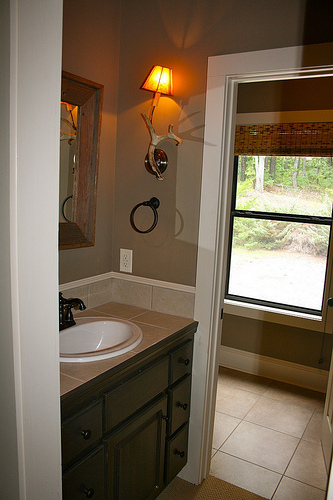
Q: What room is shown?
A: Bathroom.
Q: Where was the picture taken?
A: In a bathroom.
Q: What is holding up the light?
A: A antler.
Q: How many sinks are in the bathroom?
A: 1.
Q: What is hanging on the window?
A: Blinds.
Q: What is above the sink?
A: A mirror.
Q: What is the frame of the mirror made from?
A: Wood.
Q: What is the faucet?
A: Black.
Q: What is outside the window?
A: Trees.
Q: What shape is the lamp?
A: Antlers.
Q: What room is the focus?
A: Bathroom.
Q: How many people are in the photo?
A: Zero.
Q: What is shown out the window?
A: Trees.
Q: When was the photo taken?
A: Morning.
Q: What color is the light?
A: Orange.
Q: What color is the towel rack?
A: Bronze.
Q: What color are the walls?
A: Tan.